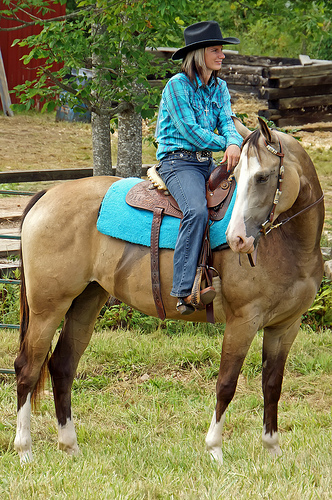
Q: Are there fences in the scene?
A: Yes, there is a fence.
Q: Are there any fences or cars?
A: Yes, there is a fence.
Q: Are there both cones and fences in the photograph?
A: No, there is a fence but no cones.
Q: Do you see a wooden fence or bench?
A: Yes, there is a wood fence.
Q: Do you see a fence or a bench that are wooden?
A: Yes, the fence is wooden.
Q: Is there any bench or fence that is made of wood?
A: Yes, the fence is made of wood.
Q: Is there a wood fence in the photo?
A: Yes, there is a wood fence.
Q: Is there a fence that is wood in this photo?
A: Yes, there is a wood fence.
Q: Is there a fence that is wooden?
A: Yes, there is a fence that is wooden.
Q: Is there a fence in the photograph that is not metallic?
A: Yes, there is a wooden fence.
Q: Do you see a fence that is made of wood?
A: Yes, there is a fence that is made of wood.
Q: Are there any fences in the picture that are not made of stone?
A: Yes, there is a fence that is made of wood.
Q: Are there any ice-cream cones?
A: No, there are no ice-cream cones.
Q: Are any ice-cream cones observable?
A: No, there are no ice-cream cones.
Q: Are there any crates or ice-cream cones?
A: No, there are no ice-cream cones or crates.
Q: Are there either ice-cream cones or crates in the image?
A: No, there are no ice-cream cones or crates.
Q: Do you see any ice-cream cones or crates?
A: No, there are no ice-cream cones or crates.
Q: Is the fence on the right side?
A: Yes, the fence is on the right of the image.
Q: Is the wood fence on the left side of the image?
A: No, the fence is on the right of the image.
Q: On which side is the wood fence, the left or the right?
A: The fence is on the right of the image.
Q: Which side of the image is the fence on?
A: The fence is on the right of the image.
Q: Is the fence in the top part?
A: Yes, the fence is in the top of the image.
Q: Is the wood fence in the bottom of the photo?
A: No, the fence is in the top of the image.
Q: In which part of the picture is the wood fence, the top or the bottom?
A: The fence is in the top of the image.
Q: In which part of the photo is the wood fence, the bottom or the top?
A: The fence is in the top of the image.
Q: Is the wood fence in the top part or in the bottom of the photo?
A: The fence is in the top of the image.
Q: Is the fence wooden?
A: Yes, the fence is wooden.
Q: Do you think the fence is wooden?
A: Yes, the fence is wooden.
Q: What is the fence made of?
A: The fence is made of wood.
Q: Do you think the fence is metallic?
A: No, the fence is wooden.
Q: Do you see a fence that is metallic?
A: No, there is a fence but it is wooden.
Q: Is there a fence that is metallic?
A: No, there is a fence but it is wooden.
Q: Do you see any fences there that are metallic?
A: No, there is a fence but it is wooden.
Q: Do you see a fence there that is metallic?
A: No, there is a fence but it is wooden.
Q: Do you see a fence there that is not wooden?
A: No, there is a fence but it is wooden.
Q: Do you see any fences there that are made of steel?
A: No, there is a fence but it is made of wood.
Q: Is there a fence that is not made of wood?
A: No, there is a fence but it is made of wood.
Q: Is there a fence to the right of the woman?
A: Yes, there is a fence to the right of the woman.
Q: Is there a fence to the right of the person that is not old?
A: Yes, there is a fence to the right of the woman.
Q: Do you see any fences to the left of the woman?
A: No, the fence is to the right of the woman.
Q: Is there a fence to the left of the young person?
A: No, the fence is to the right of the woman.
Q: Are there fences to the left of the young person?
A: No, the fence is to the right of the woman.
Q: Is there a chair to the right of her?
A: No, there is a fence to the right of the woman.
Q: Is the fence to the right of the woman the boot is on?
A: Yes, the fence is to the right of the woman.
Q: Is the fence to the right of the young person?
A: Yes, the fence is to the right of the woman.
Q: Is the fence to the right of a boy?
A: No, the fence is to the right of the woman.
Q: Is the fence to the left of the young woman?
A: No, the fence is to the right of the woman.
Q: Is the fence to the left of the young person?
A: No, the fence is to the right of the woman.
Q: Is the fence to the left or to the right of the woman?
A: The fence is to the right of the woman.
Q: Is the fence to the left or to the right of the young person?
A: The fence is to the right of the woman.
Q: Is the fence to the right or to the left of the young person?
A: The fence is to the right of the woman.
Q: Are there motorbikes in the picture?
A: No, there are no motorbikes.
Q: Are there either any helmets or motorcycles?
A: No, there are no motorcycles or helmets.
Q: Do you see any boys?
A: No, there are no boys.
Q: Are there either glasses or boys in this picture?
A: No, there are no boys or glasses.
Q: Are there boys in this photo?
A: No, there are no boys.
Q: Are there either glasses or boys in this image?
A: No, there are no boys or glasses.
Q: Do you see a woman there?
A: Yes, there is a woman.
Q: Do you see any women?
A: Yes, there is a woman.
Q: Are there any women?
A: Yes, there is a woman.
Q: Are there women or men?
A: Yes, there is a woman.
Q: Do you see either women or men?
A: Yes, there is a woman.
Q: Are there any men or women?
A: Yes, there is a woman.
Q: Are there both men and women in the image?
A: No, there is a woman but no men.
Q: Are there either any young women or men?
A: Yes, there is a young woman.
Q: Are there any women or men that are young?
A: Yes, the woman is young.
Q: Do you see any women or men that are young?
A: Yes, the woman is young.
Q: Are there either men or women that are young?
A: Yes, the woman is young.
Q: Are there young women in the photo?
A: Yes, there is a young woman.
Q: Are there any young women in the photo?
A: Yes, there is a young woman.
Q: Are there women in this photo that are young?
A: Yes, there is a woman that is young.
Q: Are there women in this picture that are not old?
A: Yes, there is an young woman.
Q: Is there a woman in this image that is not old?
A: Yes, there is an young woman.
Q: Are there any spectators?
A: No, there are no spectators.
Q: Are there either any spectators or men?
A: No, there are no spectators or men.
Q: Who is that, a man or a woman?
A: That is a woman.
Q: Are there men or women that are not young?
A: No, there is a woman but she is young.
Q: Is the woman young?
A: Yes, the woman is young.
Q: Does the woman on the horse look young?
A: Yes, the woman is young.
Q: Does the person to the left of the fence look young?
A: Yes, the woman is young.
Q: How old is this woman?
A: The woman is young.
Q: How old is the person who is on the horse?
A: The woman is young.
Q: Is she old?
A: No, the woman is young.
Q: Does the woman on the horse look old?
A: No, the woman is young.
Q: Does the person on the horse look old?
A: No, the woman is young.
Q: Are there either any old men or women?
A: No, there is a woman but she is young.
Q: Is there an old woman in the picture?
A: No, there is a woman but she is young.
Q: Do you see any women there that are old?
A: No, there is a woman but she is young.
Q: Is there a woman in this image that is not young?
A: No, there is a woman but she is young.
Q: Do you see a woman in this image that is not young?
A: No, there is a woman but she is young.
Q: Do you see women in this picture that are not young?
A: No, there is a woman but she is young.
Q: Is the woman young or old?
A: The woman is young.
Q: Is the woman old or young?
A: The woman is young.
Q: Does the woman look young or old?
A: The woman is young.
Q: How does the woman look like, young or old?
A: The woman is young.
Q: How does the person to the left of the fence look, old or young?
A: The woman is young.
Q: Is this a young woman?
A: Yes, this is a young woman.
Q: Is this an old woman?
A: No, this is a young woman.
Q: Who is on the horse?
A: The woman is on the horse.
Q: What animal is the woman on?
A: The woman is on the horse.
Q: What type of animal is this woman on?
A: The woman is on the horse.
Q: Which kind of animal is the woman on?
A: The woman is on the horse.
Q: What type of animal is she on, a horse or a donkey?
A: The woman is on a horse.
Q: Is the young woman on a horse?
A: Yes, the woman is on a horse.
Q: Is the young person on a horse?
A: Yes, the woman is on a horse.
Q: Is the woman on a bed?
A: No, the woman is on a horse.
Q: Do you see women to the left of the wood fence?
A: Yes, there is a woman to the left of the fence.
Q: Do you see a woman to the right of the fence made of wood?
A: No, the woman is to the left of the fence.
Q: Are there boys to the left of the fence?
A: No, there is a woman to the left of the fence.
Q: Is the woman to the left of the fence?
A: Yes, the woman is to the left of the fence.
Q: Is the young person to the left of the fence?
A: Yes, the woman is to the left of the fence.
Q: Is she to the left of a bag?
A: No, the woman is to the left of the fence.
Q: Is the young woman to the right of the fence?
A: No, the woman is to the left of the fence.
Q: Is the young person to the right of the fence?
A: No, the woman is to the left of the fence.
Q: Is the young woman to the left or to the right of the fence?
A: The woman is to the left of the fence.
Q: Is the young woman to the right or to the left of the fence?
A: The woman is to the left of the fence.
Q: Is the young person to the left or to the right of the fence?
A: The woman is to the left of the fence.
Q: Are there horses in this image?
A: Yes, there is a horse.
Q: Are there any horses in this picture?
A: Yes, there is a horse.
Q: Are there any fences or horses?
A: Yes, there is a horse.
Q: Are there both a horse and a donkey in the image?
A: No, there is a horse but no donkeys.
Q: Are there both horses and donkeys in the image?
A: No, there is a horse but no donkeys.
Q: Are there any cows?
A: No, there are no cows.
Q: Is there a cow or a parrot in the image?
A: No, there are no cows or parrots.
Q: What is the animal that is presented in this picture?
A: The animal is a horse.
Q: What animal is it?
A: The animal is a horse.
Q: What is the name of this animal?
A: This is a horse.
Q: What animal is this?
A: This is a horse.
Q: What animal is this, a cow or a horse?
A: This is a horse.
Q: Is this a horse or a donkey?
A: This is a horse.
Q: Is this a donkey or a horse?
A: This is a horse.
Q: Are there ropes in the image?
A: No, there are no ropes.